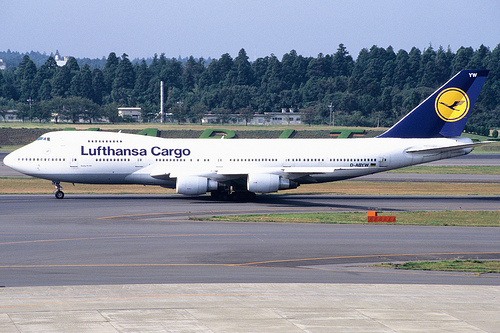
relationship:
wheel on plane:
[49, 186, 66, 201] [5, 94, 472, 221]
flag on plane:
[369, 162, 379, 169] [0, 58, 495, 208]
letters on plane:
[81, 143, 193, 160] [4, 67, 498, 201]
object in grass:
[365, 205, 397, 226] [188, 209, 498, 229]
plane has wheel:
[2, 70, 489, 197] [48, 169, 126, 194]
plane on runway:
[2, 70, 489, 197] [0, 193, 498, 280]